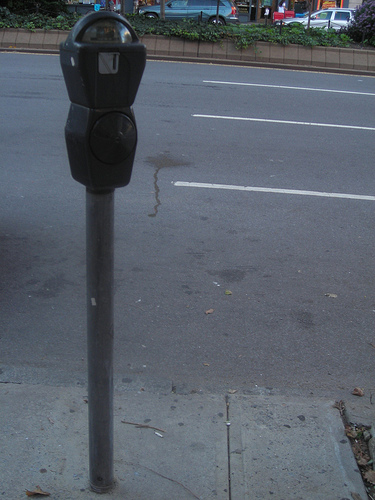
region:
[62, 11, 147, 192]
meter with hour glass figure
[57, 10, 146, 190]
an invention from Oklahoma City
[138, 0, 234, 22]
an SUV or crossover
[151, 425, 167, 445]
litter by a tobacco addict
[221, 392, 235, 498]
a joint in the sidewalk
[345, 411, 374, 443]
leaves near the sidewalk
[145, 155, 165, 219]
a crack in the road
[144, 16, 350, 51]
bushes in a planter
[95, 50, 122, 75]
a slot for the coins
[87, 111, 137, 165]
the lid to the coin container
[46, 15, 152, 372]
this is a mail box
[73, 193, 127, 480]
the pole is straight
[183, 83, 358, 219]
white strips are on the road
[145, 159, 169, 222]
the road is cracky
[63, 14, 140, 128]
the mail box is shiny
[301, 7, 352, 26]
the cars are parked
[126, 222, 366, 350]
the road is tarmacked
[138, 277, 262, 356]
the road is dirty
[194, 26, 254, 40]
the leaves are green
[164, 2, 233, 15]
the car is grey in color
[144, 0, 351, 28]
these are two cars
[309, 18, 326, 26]
the car is grey in color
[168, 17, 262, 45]
this is the grass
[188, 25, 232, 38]
the grass is green in color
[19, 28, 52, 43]
this is a wall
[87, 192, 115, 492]
this is a pole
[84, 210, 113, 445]
the pole is metallic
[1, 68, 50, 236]
this is the road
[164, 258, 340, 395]
the road is clear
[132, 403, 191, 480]
this is a pavement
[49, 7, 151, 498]
parking meter on sidewalk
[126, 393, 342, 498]
concrete sidewalk next to road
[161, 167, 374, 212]
white painted line in the road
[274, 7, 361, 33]
silver car parked across street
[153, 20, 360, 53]
bushes along side of street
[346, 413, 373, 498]
dirt and mulch next to sidewalk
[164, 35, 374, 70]
concrete median by the street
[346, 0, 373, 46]
purple floral bush along side of road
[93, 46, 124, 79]
coin slot for parking meter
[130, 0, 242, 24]
blue minivan along side of street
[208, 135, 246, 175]
part of a road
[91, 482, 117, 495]
base of a post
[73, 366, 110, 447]
part of a post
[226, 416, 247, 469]
part of a line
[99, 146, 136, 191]
part of a black top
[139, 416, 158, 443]
part of a dry stick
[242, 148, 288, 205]
part of a white line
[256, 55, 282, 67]
edge of a road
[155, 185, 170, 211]
part of some spill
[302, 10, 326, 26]
side mirror of a car